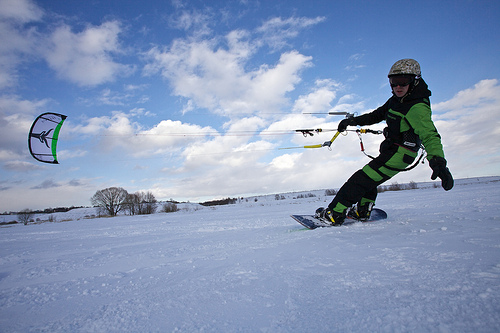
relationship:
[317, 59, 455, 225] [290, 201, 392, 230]
person has a snowboard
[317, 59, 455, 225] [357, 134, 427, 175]
snowboarder has a rope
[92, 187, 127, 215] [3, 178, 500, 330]
tree in snow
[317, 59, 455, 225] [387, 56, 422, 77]
person wearing a helmet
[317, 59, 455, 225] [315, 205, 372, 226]
person has shoes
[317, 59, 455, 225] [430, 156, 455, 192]
person has a glove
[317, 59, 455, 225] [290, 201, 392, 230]
person on a snowboard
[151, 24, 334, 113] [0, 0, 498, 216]
clouds are in sky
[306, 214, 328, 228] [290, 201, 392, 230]
snow on snowboard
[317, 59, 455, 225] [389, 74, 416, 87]
person wearing goggles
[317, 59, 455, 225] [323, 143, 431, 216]
person has a leg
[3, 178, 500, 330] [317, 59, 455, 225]
snow under person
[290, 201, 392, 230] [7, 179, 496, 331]
snowboard on ground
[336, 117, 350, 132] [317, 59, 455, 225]
hand of person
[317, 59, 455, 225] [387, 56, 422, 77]
person has a helmet